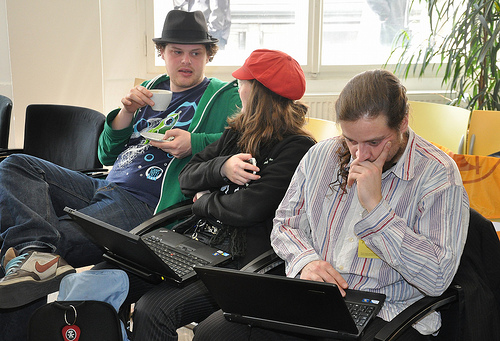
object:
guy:
[0, 9, 239, 341]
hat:
[153, 9, 220, 43]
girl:
[74, 49, 314, 341]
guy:
[189, 69, 466, 340]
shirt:
[269, 126, 467, 337]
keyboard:
[339, 282, 383, 326]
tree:
[383, 0, 500, 110]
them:
[0, 12, 467, 341]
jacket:
[171, 127, 314, 269]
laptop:
[61, 206, 232, 289]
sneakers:
[3, 253, 76, 299]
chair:
[0, 104, 107, 175]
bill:
[232, 49, 306, 100]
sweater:
[99, 77, 243, 214]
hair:
[323, 69, 409, 202]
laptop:
[193, 266, 387, 340]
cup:
[144, 90, 172, 111]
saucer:
[140, 133, 175, 143]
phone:
[229, 158, 256, 184]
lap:
[123, 231, 235, 287]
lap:
[263, 282, 390, 339]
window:
[155, 0, 310, 65]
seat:
[401, 101, 470, 153]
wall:
[6, 5, 103, 114]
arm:
[135, 203, 191, 240]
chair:
[157, 131, 237, 218]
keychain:
[58, 303, 79, 337]